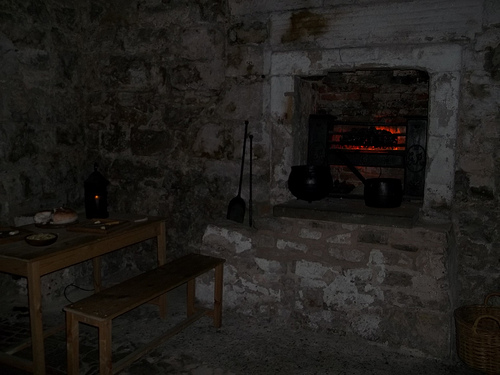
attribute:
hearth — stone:
[198, 200, 457, 353]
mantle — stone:
[260, 40, 467, 215]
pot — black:
[334, 154, 406, 213]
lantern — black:
[75, 159, 112, 223]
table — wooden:
[4, 199, 171, 372]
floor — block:
[4, 286, 457, 373]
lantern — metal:
[79, 156, 119, 222]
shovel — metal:
[220, 118, 252, 225]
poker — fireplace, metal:
[240, 129, 259, 228]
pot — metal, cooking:
[339, 161, 409, 209]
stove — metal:
[300, 106, 420, 209]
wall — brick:
[200, 207, 480, 366]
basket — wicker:
[450, 301, 495, 371]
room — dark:
[4, 1, 493, 370]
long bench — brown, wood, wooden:
[62, 251, 231, 374]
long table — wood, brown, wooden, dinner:
[2, 199, 168, 374]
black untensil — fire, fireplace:
[217, 103, 264, 234]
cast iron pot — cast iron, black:
[277, 154, 338, 208]